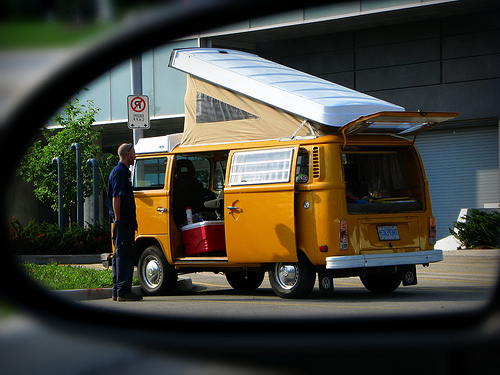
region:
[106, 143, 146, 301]
man standing near yellow van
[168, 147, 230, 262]
door open on yellow van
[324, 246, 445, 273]
white bumper on back of van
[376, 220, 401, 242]
white license plate on back of van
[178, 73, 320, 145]
large tan pop-up on top of van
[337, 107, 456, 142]
back door of van up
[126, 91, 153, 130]
white and red sign in front of van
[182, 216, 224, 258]
red cooler inside van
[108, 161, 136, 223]
man wearing blue shirt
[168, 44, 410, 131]
white roof of yellow van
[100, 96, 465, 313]
Yellow van parked on a parking lot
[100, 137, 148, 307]
Man standing in front of van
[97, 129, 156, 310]
Man wears a blue shirt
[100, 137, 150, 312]
Man wears blue jeans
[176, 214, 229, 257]
Red box in van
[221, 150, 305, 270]
Door of van is open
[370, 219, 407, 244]
White plate of van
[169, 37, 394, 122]
Roof of van is open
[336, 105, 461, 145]
Back window is open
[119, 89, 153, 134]
Street sign in front of van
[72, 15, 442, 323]
man standing by yellow van parked in lot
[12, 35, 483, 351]
image reflected on a mirror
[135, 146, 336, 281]
door of van slid open to back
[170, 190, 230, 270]
red and white cooler inside the van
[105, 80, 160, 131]
parking sign shown in reverse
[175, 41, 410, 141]
van roof elevated at an angle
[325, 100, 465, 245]
back door lifted open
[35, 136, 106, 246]
dark blue curved pipes in plantings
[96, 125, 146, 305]
man dressed in dark blue looking into the van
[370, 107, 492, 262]
closed metal gate on building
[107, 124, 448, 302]
Orange van in front of building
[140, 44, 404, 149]
Yellow van has white roof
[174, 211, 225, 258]
Red box with white cover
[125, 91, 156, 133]
Street sign on a pole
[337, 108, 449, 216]
Back window of van is open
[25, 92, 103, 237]
A tree in front of building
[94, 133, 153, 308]
Man is blond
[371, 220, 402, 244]
Tag of van is white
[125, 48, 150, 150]
Grey pole supporting a sign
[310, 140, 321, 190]
Vents of van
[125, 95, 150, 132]
a parking sign is on a pole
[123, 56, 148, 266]
a pole holding a sign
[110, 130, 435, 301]
an orange van is parked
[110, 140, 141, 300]
a man is standing in front of a van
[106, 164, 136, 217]
the man is wearing a dark blue shirt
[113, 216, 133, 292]
the man is wearing dark pants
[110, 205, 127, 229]
the man has his hand in back pocket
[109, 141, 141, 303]
the man is looking into the van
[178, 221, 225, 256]
a red and white cooler is in the van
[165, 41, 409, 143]
the top of the van is raised